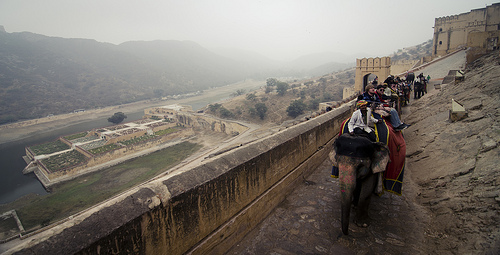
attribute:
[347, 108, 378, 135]
jacket — white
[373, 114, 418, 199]
cloth — red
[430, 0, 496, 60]
building — beige